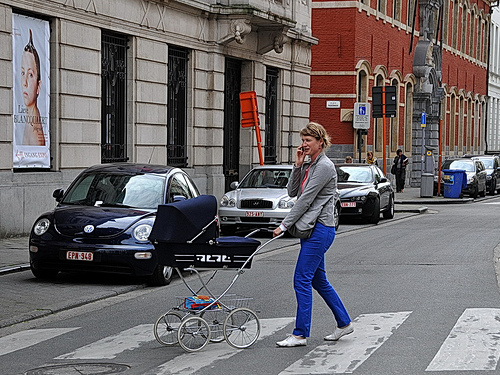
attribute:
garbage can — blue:
[442, 170, 465, 197]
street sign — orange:
[241, 90, 257, 128]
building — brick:
[312, 7, 496, 154]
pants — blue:
[271, 218, 357, 341]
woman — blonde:
[297, 117, 329, 144]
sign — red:
[232, 88, 281, 139]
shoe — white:
[273, 324, 313, 357]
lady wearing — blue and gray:
[268, 120, 372, 362]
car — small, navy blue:
[24, 142, 234, 301]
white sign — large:
[9, 12, 55, 169]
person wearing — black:
[391, 147, 413, 194]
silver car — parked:
[220, 156, 348, 261]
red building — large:
[333, 14, 472, 141]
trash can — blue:
[440, 165, 466, 195]